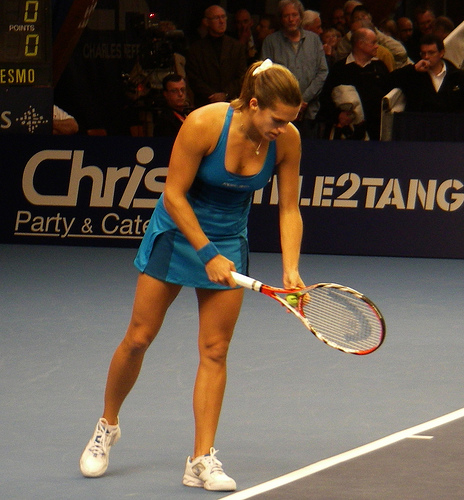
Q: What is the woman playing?
A: Tennis.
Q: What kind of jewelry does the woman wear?
A: Gold necklace.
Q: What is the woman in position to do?
A: Serve the ball.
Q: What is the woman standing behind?
A: The white line.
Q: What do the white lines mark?
A: Tennis court boundaries.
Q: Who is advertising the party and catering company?
A: Chris.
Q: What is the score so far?
A: 0-0.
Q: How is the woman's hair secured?
A: White scrunchie.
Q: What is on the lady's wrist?
A: Blue sweatband.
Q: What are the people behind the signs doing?
A: Watching the tennis game.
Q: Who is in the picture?
A: A woman.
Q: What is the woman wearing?
A: Blue dress.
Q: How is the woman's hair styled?
A: In a ponytail.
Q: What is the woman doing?
A: Playing tennis.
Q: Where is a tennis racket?
A: In player's hand.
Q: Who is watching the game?
A: Spectators.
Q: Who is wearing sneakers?
A: Tennis player.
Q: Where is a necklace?
A: Around woman's neck.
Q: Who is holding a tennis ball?
A: The woman.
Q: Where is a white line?
A: On the court.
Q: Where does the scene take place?
A: At a tennis game.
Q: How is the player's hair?
A: In a ponytail.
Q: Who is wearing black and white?
A: Spectator on the right.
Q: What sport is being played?
A: Tennis.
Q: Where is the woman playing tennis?
A: Tennis court.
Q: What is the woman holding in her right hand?
A: Tennis racket.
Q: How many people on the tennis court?
A: One.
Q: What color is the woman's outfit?
A: Blue.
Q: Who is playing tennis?
A: A woman.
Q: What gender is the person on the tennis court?
A: Female.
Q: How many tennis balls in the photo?
A: One.